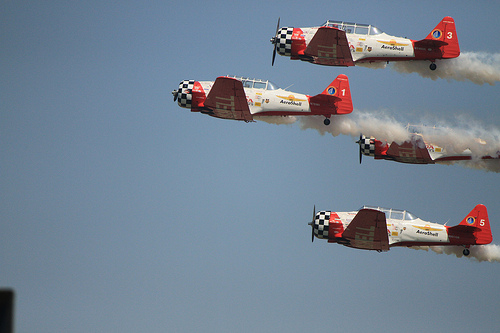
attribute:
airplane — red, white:
[161, 72, 360, 129]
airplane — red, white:
[164, 69, 351, 129]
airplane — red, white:
[172, 70, 358, 134]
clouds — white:
[299, 88, 494, 162]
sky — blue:
[5, 3, 495, 327]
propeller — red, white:
[168, 87, 182, 102]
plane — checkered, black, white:
[154, 62, 379, 154]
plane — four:
[263, 13, 463, 76]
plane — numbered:
[350, 117, 500, 169]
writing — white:
[209, 88, 239, 122]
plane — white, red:
[287, 197, 494, 267]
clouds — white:
[1, 1, 174, 247]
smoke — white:
[238, 104, 496, 160]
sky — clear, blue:
[13, 21, 142, 309]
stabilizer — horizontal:
[449, 222, 480, 239]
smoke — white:
[411, 240, 498, 262]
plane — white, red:
[138, 57, 393, 157]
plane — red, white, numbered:
[167, 64, 357, 129]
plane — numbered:
[270, 8, 462, 73]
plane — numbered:
[305, 197, 497, 258]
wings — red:
[344, 206, 390, 256]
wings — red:
[212, 71, 246, 143]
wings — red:
[390, 124, 434, 183]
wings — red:
[305, 19, 361, 75]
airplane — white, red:
[129, 44, 365, 149]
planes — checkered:
[116, 19, 498, 303]